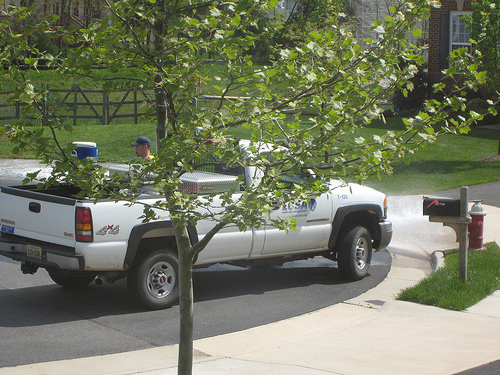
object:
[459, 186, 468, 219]
top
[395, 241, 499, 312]
patch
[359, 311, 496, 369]
sidewalk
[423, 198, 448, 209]
flag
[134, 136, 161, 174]
man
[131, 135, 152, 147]
cap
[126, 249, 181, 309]
tire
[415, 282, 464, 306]
grass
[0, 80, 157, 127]
fence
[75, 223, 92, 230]
light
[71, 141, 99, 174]
cooler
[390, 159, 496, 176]
shadows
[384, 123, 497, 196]
lawn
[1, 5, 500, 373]
tree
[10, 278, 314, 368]
road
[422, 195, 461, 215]
mailbox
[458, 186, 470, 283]
post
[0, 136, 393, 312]
truck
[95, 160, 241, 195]
box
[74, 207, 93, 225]
light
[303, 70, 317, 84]
leaves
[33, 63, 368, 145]
yard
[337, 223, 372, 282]
truck tire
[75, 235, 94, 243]
tail light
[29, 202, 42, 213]
handle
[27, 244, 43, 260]
license plate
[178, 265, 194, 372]
trunk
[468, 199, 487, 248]
fire hydrant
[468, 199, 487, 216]
top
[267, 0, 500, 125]
house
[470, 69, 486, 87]
leaves